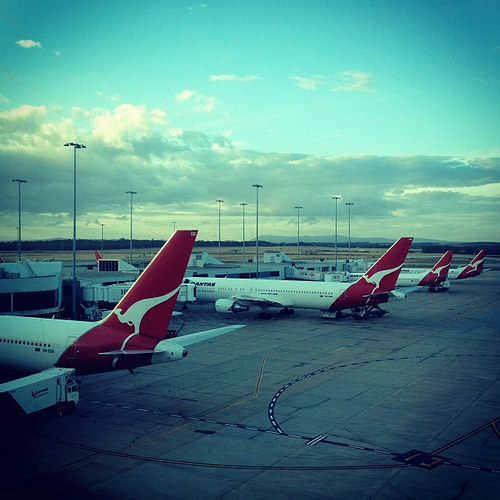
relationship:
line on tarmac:
[151, 391, 256, 446] [1, 268, 496, 497]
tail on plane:
[350, 236, 416, 319] [180, 233, 415, 323]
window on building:
[266, 269, 282, 281] [1, 257, 367, 332]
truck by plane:
[426, 275, 455, 294] [180, 233, 415, 323]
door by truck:
[64, 336, 78, 361] [426, 275, 455, 294]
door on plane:
[64, 336, 78, 361] [180, 233, 415, 323]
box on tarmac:
[400, 449, 450, 470] [1, 268, 496, 497]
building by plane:
[1, 257, 367, 332] [180, 233, 415, 323]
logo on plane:
[112, 281, 178, 353] [180, 233, 415, 323]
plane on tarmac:
[180, 233, 415, 323] [1, 268, 496, 497]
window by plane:
[266, 269, 282, 281] [180, 233, 415, 323]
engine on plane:
[211, 296, 249, 316] [180, 233, 415, 323]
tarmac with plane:
[1, 268, 496, 497] [180, 233, 415, 323]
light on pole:
[64, 138, 78, 147] [70, 147, 79, 323]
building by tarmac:
[1, 257, 367, 332] [1, 268, 496, 497]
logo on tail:
[112, 281, 178, 353] [350, 236, 416, 319]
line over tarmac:
[151, 391, 256, 446] [1, 268, 496, 497]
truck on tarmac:
[426, 275, 455, 294] [1, 268, 496, 497]